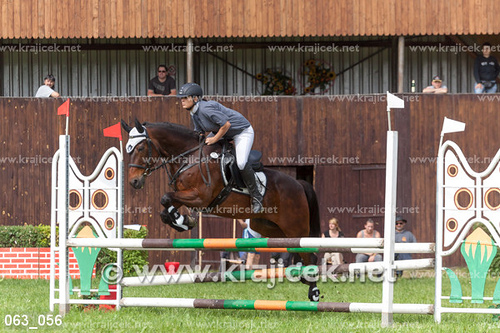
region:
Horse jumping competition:
[4, 6, 496, 327]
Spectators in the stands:
[6, 42, 496, 103]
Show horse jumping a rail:
[111, 78, 336, 307]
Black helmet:
[173, 78, 205, 102]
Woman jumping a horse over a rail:
[115, 81, 328, 307]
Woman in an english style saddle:
[175, 80, 268, 220]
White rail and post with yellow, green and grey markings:
[41, 110, 406, 320]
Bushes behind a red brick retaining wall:
[1, 224, 96, 276]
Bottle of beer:
[408, 78, 418, 95]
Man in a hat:
[382, 213, 419, 275]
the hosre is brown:
[144, 111, 331, 253]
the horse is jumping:
[104, 104, 325, 220]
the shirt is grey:
[196, 103, 261, 145]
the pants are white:
[225, 136, 260, 167]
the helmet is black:
[180, 78, 201, 96]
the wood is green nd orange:
[119, 229, 359, 259]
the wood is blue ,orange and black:
[177, 287, 358, 317]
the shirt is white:
[36, 80, 53, 96]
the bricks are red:
[12, 251, 51, 276]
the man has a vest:
[352, 215, 389, 281]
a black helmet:
[178, 81, 203, 106]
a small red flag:
[94, 122, 126, 147]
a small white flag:
[438, 115, 468, 135]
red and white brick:
[0, 248, 78, 278]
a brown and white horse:
[108, 112, 328, 307]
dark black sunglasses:
[155, 66, 171, 73]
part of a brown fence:
[1, 1, 498, 39]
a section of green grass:
[2, 278, 47, 331]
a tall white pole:
[382, 132, 399, 324]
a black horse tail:
[301, 177, 325, 237]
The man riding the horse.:
[149, 85, 326, 277]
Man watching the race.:
[148, 55, 193, 108]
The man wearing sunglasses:
[156, 67, 173, 74]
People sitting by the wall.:
[323, 208, 425, 276]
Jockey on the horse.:
[154, 41, 263, 181]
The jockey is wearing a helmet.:
[174, 78, 208, 100]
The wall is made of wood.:
[328, 93, 463, 220]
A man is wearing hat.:
[393, 217, 407, 223]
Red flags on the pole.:
[34, 96, 85, 148]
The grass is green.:
[154, 270, 390, 331]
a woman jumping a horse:
[116, 70, 323, 238]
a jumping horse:
[98, 88, 344, 258]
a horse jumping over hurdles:
[73, 69, 391, 306]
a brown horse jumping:
[98, 75, 371, 296]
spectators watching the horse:
[38, 33, 493, 113]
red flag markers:
[43, 91, 123, 134]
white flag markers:
[375, 79, 485, 140]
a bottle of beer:
[408, 73, 420, 93]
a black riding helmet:
[166, 78, 217, 95]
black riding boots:
[230, 160, 290, 220]